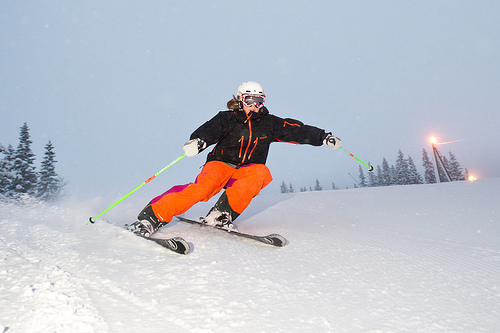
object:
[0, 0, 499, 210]
blue sky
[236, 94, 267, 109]
snow goggles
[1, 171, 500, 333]
snow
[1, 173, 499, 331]
ground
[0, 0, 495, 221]
background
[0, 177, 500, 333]
hill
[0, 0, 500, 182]
clouds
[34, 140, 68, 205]
trees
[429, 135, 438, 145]
light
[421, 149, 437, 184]
tree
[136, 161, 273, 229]
pant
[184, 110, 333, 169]
jacket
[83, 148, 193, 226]
pole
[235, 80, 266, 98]
helmet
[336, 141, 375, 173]
ski pole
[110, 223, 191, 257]
ski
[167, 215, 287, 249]
ski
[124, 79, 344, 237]
person